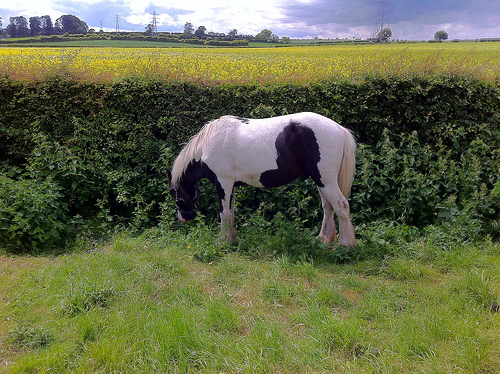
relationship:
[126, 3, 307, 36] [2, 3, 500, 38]
cloud in sky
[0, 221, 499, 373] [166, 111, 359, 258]
grass near horse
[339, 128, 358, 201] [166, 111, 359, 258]
tail on horse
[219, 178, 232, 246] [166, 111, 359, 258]
front leg of horse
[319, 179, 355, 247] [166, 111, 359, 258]
back leg of horse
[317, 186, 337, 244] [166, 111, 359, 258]
back leg of horse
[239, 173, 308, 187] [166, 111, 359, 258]
stomach of horse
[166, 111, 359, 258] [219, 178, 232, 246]
horse has a front leg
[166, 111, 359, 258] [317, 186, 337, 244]
horse has a back leg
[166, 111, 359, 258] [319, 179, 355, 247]
horse has a back leg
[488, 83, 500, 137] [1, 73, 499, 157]
edge of a bush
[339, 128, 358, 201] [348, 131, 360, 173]
tail has an edge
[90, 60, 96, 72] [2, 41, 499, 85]
flower in a field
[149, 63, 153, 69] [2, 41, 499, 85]
flower in a field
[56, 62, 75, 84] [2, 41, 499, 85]
weed in field